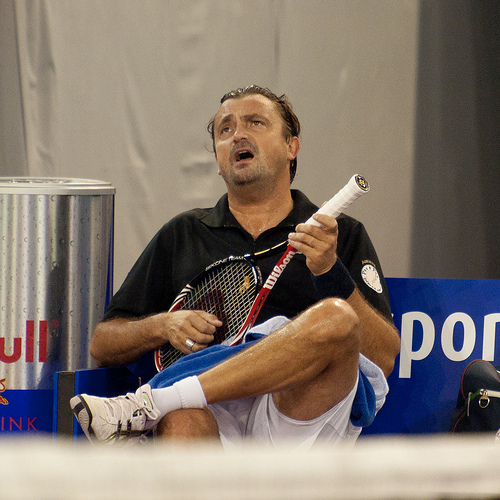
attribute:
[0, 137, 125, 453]
advertising — large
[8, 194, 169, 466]
can — red bull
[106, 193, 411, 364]
shirt — black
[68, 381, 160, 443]
white shoe — white and black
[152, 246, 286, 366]
tennis racket — red, black, and white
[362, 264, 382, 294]
circle — white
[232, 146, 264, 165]
mouth — open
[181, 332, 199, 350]
ring — silver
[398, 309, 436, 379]
letter p — white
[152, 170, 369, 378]
racket — white, black, red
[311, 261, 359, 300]
sweatband — black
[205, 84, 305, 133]
hair — short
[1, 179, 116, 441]
can — redbull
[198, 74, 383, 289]
man — slicked back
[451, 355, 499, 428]
bag — athletic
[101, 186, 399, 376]
shirt — black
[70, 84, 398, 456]
guy — brown haired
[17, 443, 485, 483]
top — white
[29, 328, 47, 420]
part — blue